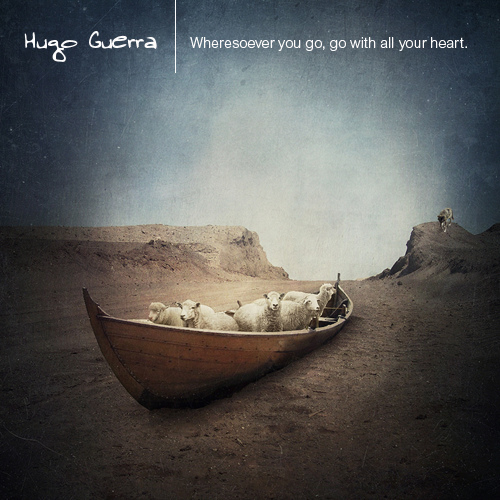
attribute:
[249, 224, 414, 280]
opening — large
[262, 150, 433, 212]
skies — blue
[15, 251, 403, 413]
boat — wooden, planked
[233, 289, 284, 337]
animal — white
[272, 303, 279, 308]
nose — black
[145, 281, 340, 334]
sheep — white, not sheared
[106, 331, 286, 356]
lines — horizontal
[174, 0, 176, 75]
line — short, white, vertical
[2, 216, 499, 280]
ridges — dark, light grey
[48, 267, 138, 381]
boat tip — triangular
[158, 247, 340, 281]
road — dirt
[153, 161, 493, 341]
earth depression — naturally formed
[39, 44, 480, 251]
sky — dark, light blue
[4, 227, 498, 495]
partition — rocky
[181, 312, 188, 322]
nose — black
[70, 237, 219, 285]
row — raised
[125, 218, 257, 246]
row — raised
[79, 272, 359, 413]
boat — wood, full